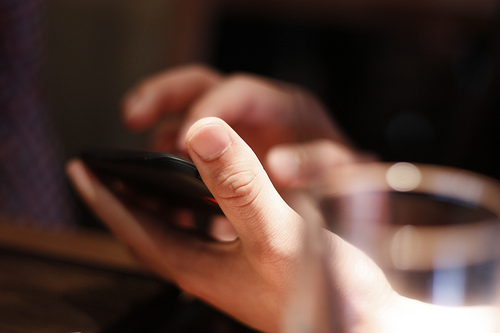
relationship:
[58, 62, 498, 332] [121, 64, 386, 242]
person has hand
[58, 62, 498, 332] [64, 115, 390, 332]
person has hand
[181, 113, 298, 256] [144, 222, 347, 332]
thumb on left hand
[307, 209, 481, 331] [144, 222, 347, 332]
person has left hand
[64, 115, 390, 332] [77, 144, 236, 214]
hand holding cell phone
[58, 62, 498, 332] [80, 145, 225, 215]
person holding phone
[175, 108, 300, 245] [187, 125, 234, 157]
thumb has nail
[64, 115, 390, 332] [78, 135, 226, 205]
hand holding cellphone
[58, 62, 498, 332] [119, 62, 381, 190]
person has hand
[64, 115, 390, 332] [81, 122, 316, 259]
hand holding phone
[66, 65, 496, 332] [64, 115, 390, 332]
woman has hand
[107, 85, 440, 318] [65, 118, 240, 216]
hand holding phone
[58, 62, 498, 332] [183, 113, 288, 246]
person has thumb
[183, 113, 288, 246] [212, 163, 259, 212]
thumb has wrinkles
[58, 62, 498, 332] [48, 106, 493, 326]
person has hand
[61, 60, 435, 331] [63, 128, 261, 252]
hands holding cell phone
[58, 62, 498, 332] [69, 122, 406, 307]
person has hand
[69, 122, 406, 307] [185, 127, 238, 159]
hand has thumb nail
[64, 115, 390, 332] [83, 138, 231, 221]
hand holding phone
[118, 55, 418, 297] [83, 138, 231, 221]
hand holding phone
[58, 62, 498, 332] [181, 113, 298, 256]
person has thumb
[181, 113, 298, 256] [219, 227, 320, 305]
thumb has knuckle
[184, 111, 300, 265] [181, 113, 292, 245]
person has finger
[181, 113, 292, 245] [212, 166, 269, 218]
finger has creases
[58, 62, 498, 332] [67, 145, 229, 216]
person holding phone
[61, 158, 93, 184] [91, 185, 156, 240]
tip of finger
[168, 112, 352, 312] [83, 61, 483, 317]
finger of person